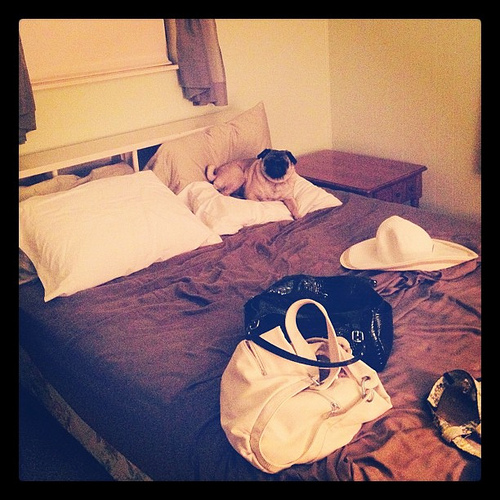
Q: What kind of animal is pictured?
A: Dog.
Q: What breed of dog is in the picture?
A: Pug.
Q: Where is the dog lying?
A: On the bed.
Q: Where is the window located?
A: Above the headboard.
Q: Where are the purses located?
A: On front right corner of the bed.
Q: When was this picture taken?
A: Early evening.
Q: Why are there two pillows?
A: It's a double bed.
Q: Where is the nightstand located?
A: Upper right side by bed.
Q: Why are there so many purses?
A: Two women in the room.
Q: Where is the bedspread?
A: Bunched at foot of bed.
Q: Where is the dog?
A: On the pillow.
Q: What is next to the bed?
A: A table.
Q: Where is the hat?
A: On the bed.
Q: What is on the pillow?
A: A dog.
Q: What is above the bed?
A: Curtains.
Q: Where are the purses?
A: On the bed.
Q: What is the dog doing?
A: Lying on a pillow.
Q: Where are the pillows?
A: On the bed.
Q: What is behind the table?
A: The wall.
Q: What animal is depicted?
A: Dog.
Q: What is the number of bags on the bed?
A: 2.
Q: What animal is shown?
A: A dog.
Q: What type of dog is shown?
A: A pug.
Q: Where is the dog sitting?
A: A pillow.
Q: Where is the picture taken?
A: A bedroom.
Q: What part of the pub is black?
A: Face.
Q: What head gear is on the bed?
A: Straw hat.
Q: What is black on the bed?
A: The purse.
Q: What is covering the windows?
A: Blinds.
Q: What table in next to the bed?
A: Nightstand.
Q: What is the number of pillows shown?
A: 4.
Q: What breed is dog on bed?
A: A pug.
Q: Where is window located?
A: Above bed.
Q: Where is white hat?
A: On bed.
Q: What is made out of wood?
A: Night stand.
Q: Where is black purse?
A: On the bed.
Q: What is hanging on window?
A: Curtains.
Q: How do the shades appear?
A: They are down.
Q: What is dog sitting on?
A: A pillow.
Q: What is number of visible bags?
A: Two.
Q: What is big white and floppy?
A: The hat.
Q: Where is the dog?
A: On a pillow.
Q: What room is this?
A: Bedroom.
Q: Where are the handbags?
A: On the bed.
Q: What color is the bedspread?
A: Brown.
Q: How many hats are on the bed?
A: One.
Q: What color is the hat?
A: White.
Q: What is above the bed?
A: A window.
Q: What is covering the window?
A: A blind.